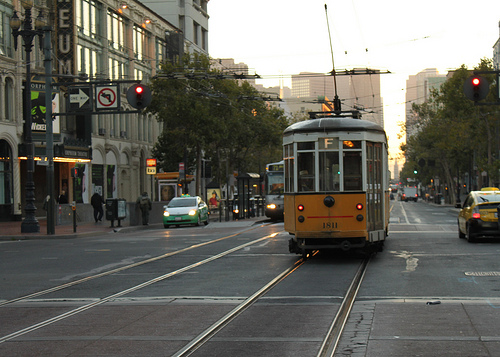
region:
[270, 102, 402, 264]
a yellow and white streetcar on the road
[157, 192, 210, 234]
a green and white cab on the side of the road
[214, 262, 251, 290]
black asphalt surface of the street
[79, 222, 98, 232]
brown brick surface of the sidewalk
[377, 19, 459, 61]
cloudy white skies over the city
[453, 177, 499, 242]
black and yellow cab on the side of the road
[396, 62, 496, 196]
trees growing next to the road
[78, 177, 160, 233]
two people walking on the sidewalk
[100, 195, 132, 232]
a newspaper box on the sidewalk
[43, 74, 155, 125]
street signs and a stoplight over the road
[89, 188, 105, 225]
the person is walking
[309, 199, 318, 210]
the strret car is orange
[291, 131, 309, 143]
the street car is white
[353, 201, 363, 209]
the light is red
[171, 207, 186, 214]
the car is green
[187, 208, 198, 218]
the light is yellow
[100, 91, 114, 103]
the arrow is black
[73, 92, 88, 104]
the arrow is white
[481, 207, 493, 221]
the cab is yellow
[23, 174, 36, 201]
the pole is black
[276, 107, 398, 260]
a yellow and white trolley in the street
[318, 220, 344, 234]
black numbers on the yellow front of the trolley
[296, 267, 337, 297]
black asphalt surface of the street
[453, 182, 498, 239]
yellow and black cab on the side of the street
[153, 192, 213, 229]
white and green cab on the side of the street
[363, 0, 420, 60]
white cloudy skies over the city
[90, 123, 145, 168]
white concrete wall of the building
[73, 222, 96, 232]
red brick surface of the sidewalk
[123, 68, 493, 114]
red stoplights over the road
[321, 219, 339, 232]
the black number on the front of the bus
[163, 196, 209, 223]
a small green car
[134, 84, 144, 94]
a red traffic light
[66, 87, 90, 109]
a white arrow pointing right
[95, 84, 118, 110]
a no left turn sign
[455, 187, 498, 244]
the back of a yellow car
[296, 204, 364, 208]
red headlights on the front of the bus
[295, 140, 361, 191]
the paneled front windows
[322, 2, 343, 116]
a tall antennae on top of the tram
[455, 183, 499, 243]
Yellow and black prius taxi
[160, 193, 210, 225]
Green and white prius taxi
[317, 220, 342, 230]
Train ID number 1811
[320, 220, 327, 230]
The number 1 on the back of a train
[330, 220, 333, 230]
The number 1 on the back of a train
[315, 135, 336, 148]
The letter F on the back of a train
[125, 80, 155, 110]
Circular stop light which is red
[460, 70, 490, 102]
Circular stop light which is red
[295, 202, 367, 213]
Rear red lights on a train